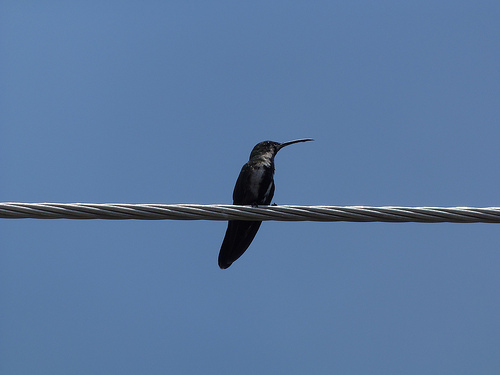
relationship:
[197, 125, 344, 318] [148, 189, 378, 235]
bird sitting on wire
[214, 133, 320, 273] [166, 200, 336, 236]
bird sitting on wire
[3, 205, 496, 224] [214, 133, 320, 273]
wire under bird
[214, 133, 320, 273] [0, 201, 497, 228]
bird on wire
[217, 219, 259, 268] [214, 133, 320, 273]
tail of bird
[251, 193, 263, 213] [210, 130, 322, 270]
foot of bird